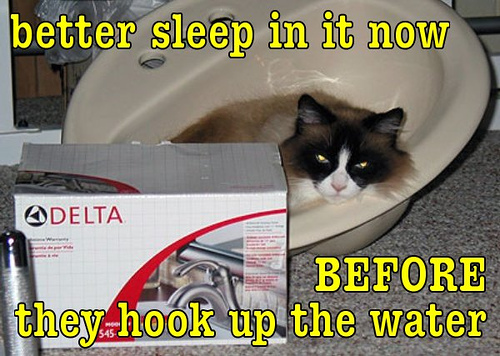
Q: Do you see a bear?
A: No, there are no bears.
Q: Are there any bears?
A: No, there are no bears.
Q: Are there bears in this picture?
A: No, there are no bears.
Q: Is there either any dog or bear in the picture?
A: No, there are no bears or dogs.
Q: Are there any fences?
A: No, there are no fences.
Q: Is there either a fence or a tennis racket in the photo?
A: No, there are no fences or rackets.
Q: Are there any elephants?
A: No, there are no elephants.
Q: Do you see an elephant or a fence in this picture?
A: No, there are no elephants or fences.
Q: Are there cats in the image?
A: Yes, there is a cat.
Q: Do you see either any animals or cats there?
A: Yes, there is a cat.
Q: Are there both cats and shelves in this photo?
A: No, there is a cat but no shelves.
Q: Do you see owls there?
A: No, there are no owls.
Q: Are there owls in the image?
A: No, there are no owls.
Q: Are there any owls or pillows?
A: No, there are no owls or pillows.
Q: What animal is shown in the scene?
A: The animal is a cat.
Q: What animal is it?
A: The animal is a cat.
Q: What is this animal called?
A: This is a cat.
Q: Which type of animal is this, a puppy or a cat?
A: This is a cat.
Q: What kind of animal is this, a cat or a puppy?
A: This is a cat.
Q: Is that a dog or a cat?
A: That is a cat.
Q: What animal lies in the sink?
A: The cat lies in the sink.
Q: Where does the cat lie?
A: The cat lies in the sink.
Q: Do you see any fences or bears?
A: No, there are no bears or fences.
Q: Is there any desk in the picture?
A: No, there are no desks.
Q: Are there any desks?
A: No, there are no desks.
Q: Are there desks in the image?
A: No, there are no desks.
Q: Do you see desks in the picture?
A: No, there are no desks.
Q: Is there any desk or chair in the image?
A: No, there are no desks or chairs.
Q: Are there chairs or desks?
A: No, there are no desks or chairs.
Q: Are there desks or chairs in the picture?
A: No, there are no desks or chairs.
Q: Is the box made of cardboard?
A: Yes, the box is made of cardboard.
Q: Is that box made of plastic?
A: No, the box is made of cardboard.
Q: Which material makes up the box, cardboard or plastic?
A: The box is made of cardboard.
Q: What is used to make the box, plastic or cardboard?
A: The box is made of cardboard.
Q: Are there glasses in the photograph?
A: No, there are no glasses.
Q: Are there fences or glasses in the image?
A: No, there are no glasses or fences.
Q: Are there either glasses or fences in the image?
A: No, there are no glasses or fences.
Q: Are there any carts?
A: No, there are no carts.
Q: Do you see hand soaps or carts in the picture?
A: No, there are no carts or hand soaps.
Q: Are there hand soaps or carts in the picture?
A: No, there are no carts or hand soaps.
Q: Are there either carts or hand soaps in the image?
A: No, there are no carts or hand soaps.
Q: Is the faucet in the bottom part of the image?
A: Yes, the faucet is in the bottom of the image.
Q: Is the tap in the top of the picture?
A: No, the tap is in the bottom of the image.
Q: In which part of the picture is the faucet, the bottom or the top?
A: The faucet is in the bottom of the image.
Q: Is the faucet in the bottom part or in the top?
A: The faucet is in the bottom of the image.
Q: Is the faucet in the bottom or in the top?
A: The faucet is in the bottom of the image.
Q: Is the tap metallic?
A: Yes, the tap is metallic.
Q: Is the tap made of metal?
A: Yes, the tap is made of metal.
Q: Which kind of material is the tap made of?
A: The tap is made of metal.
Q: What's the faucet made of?
A: The tap is made of metal.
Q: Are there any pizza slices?
A: No, there are no pizza slices.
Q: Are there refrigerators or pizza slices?
A: No, there are no pizza slices or refrigerators.